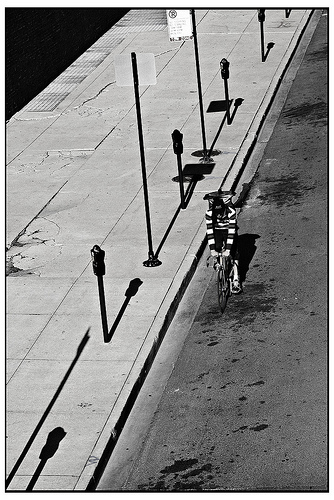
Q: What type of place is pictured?
A: It is a sidewalk.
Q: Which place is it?
A: It is a sidewalk.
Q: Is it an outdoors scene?
A: Yes, it is outdoors.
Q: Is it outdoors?
A: Yes, it is outdoors.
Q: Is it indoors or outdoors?
A: It is outdoors.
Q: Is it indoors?
A: No, it is outdoors.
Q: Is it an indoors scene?
A: No, it is outdoors.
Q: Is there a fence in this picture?
A: No, there are no fences.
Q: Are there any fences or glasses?
A: No, there are no fences or glasses.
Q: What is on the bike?
A: The shirt is on the bike.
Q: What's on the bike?
A: The shirt is on the bike.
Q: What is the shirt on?
A: The shirt is on the bike.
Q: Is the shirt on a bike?
A: Yes, the shirt is on a bike.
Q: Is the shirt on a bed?
A: No, the shirt is on a bike.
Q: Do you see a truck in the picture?
A: No, there are no trucks.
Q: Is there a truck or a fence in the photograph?
A: No, there are no trucks or fences.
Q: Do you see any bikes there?
A: Yes, there is a bike.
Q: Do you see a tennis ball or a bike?
A: Yes, there is a bike.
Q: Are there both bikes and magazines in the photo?
A: No, there is a bike but no magazines.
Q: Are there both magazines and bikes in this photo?
A: No, there is a bike but no magazines.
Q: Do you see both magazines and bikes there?
A: No, there is a bike but no magazines.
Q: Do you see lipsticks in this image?
A: No, there are no lipsticks.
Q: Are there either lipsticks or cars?
A: No, there are no lipsticks or cars.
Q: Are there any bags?
A: No, there are no bags.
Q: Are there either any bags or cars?
A: No, there are no bags or cars.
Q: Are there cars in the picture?
A: No, there are no cars.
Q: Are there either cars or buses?
A: No, there are no cars or buses.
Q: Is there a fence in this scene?
A: No, there are no fences.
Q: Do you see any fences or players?
A: No, there are no fences or players.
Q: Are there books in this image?
A: No, there are no books.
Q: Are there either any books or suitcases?
A: No, there are no books or suitcases.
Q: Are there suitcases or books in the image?
A: No, there are no books or suitcases.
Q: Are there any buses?
A: No, there are no buses.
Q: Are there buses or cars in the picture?
A: No, there are no buses or cars.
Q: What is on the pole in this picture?
A: The sign is on the pole.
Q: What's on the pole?
A: The sign is on the pole.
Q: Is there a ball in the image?
A: No, there are no balls.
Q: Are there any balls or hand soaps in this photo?
A: No, there are no balls or hand soaps.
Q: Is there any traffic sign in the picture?
A: Yes, there is a traffic sign.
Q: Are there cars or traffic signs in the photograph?
A: Yes, there is a traffic sign.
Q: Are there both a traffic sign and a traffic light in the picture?
A: No, there is a traffic sign but no traffic lights.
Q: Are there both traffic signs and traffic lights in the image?
A: No, there is a traffic sign but no traffic lights.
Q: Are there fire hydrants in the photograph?
A: No, there are no fire hydrants.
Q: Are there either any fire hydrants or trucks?
A: No, there are no fire hydrants or trucks.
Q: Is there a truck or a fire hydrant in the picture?
A: No, there are no fire hydrants or trucks.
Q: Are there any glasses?
A: No, there are no glasses.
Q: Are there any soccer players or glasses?
A: No, there are no glasses or soccer players.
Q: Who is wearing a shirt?
A: The girl is wearing a shirt.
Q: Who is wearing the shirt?
A: The girl is wearing a shirt.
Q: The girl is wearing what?
A: The girl is wearing a shirt.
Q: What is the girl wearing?
A: The girl is wearing a shirt.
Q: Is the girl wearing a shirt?
A: Yes, the girl is wearing a shirt.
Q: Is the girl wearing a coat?
A: No, the girl is wearing a shirt.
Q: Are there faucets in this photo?
A: No, there are no faucets.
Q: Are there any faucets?
A: No, there are no faucets.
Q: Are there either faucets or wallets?
A: No, there are no faucets or wallets.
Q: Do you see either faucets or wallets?
A: No, there are no faucets or wallets.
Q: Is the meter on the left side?
A: Yes, the meter is on the left of the image.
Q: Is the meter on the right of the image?
A: No, the meter is on the left of the image.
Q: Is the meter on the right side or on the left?
A: The meter is on the left of the image.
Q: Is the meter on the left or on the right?
A: The meter is on the left of the image.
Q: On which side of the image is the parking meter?
A: The parking meter is on the left of the image.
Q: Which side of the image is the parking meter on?
A: The parking meter is on the left of the image.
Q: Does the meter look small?
A: Yes, the meter is small.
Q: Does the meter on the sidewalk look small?
A: Yes, the parking meter is small.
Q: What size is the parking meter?
A: The parking meter is small.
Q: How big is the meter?
A: The meter is small.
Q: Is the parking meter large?
A: No, the parking meter is small.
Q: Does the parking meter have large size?
A: No, the parking meter is small.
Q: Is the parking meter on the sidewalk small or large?
A: The parking meter is small.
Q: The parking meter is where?
A: The parking meter is on the sidewalk.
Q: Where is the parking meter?
A: The parking meter is on the sidewalk.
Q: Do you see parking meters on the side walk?
A: Yes, there is a parking meter on the side walk.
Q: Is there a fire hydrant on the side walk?
A: No, there is a parking meter on the side walk.